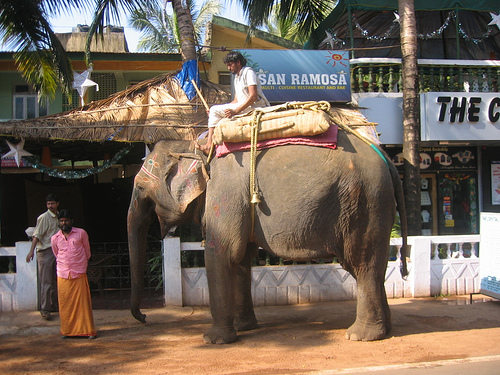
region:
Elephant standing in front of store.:
[115, 116, 403, 343]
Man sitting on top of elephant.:
[195, 51, 270, 153]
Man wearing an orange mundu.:
[51, 267, 105, 349]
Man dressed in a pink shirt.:
[45, 228, 99, 279]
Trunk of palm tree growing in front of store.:
[386, 3, 428, 239]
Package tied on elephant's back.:
[210, 99, 355, 154]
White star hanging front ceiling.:
[5, 135, 35, 173]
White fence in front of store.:
[385, 231, 476, 302]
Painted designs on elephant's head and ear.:
[136, 145, 211, 213]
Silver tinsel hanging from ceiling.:
[28, 140, 135, 185]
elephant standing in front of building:
[109, 60, 413, 350]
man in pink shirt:
[46, 206, 107, 283]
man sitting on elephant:
[199, 42, 286, 142]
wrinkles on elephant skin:
[296, 182, 343, 238]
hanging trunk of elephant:
[120, 209, 160, 328]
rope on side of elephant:
[234, 141, 271, 211]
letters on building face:
[425, 83, 497, 137]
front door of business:
[421, 166, 488, 248]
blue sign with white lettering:
[238, 43, 358, 105]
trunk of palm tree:
[399, 51, 432, 188]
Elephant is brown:
[106, 40, 425, 356]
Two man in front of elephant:
[23, 189, 110, 351]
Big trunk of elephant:
[116, 200, 163, 328]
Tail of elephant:
[386, 149, 413, 286]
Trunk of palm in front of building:
[382, 1, 431, 242]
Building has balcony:
[349, 41, 499, 150]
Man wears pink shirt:
[43, 208, 100, 343]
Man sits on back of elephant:
[192, 38, 276, 162]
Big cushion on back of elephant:
[213, 91, 367, 146]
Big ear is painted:
[164, 148, 210, 216]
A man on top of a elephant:
[201, 46, 284, 148]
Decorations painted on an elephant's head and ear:
[136, 138, 216, 209]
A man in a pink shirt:
[47, 221, 102, 290]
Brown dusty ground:
[136, 315, 298, 374]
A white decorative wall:
[391, 229, 483, 295]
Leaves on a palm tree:
[8, 4, 80, 98]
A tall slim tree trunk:
[392, 6, 440, 227]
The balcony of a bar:
[337, 38, 491, 107]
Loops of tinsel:
[346, 4, 460, 45]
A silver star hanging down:
[4, 130, 32, 172]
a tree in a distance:
[0, 7, 80, 108]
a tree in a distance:
[153, 221, 200, 303]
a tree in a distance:
[131, 6, 181, 51]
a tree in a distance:
[254, 1, 326, 40]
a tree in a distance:
[403, 2, 430, 236]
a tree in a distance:
[165, 3, 204, 78]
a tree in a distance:
[78, 1, 98, 105]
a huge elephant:
[124, 100, 399, 350]